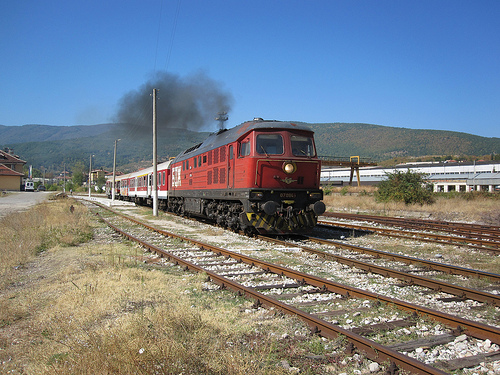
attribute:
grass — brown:
[0, 187, 499, 373]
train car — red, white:
[105, 157, 173, 209]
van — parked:
[19, 175, 39, 192]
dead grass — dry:
[1, 188, 498, 371]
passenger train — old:
[96, 112, 383, 244]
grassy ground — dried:
[0, 185, 497, 374]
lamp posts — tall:
[55, 82, 182, 219]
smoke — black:
[112, 68, 233, 155]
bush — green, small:
[371, 169, 436, 206]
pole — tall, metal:
[148, 87, 158, 215]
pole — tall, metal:
[109, 138, 118, 199]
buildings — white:
[318, 162, 499, 197]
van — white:
[23, 179, 37, 191]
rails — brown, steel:
[71, 196, 499, 375]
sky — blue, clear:
[0, 1, 494, 140]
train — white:
[102, 158, 168, 209]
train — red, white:
[109, 119, 327, 239]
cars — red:
[105, 156, 166, 205]